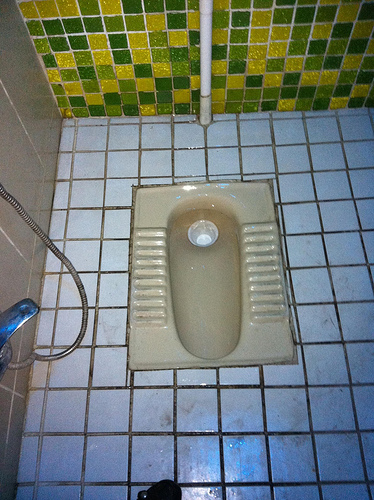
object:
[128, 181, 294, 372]
urinal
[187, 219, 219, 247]
center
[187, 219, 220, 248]
hole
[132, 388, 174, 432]
tile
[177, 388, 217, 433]
tile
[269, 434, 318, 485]
tile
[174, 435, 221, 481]
tile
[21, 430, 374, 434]
grout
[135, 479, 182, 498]
object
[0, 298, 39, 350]
handle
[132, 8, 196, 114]
tiles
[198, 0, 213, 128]
pipe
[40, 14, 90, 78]
tiles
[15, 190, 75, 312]
metal nozzle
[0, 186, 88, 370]
hose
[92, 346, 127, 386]
tile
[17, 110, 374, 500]
floor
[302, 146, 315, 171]
ridged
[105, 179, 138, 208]
tile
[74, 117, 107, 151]
tile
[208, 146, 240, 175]
tile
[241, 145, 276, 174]
tile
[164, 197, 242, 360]
grooves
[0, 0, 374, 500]
toilet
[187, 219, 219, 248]
drain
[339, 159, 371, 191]
tiles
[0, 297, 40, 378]
faucet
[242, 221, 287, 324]
feet